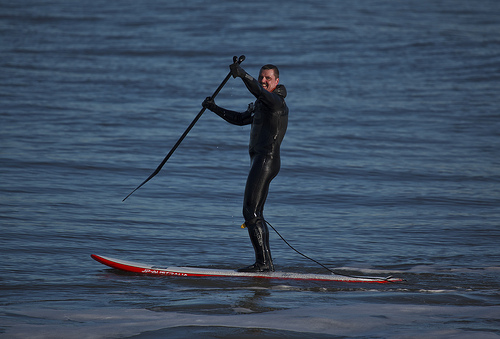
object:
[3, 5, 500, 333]
water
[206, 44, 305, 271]
man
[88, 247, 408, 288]
board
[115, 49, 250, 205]
oar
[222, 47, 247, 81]
hand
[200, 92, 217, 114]
hand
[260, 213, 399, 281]
wire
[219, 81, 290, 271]
wetsuit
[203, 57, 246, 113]
hands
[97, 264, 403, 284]
red edge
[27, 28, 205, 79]
ripples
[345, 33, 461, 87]
ripples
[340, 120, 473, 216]
ripples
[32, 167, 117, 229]
ripples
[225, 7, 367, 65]
ripples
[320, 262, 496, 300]
ripple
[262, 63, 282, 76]
hair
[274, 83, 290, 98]
hood